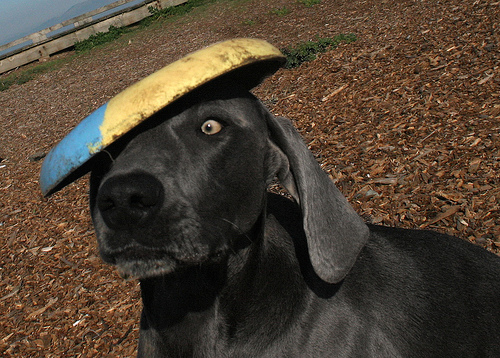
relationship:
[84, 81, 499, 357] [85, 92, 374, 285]
dog has head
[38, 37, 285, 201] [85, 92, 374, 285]
frisbee on top of head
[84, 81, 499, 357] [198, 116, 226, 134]
dog has eye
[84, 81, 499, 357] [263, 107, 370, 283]
dog has ear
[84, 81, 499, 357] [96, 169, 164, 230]
dog has nose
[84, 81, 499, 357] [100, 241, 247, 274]
dog has mouth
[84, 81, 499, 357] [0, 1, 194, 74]
dog in front of railing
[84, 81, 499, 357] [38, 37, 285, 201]
dog wearing frisbee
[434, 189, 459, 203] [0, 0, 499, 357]
wood chip on top of ground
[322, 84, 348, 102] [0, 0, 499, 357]
wood chip on top of ground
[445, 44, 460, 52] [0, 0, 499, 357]
wood chip on top of ground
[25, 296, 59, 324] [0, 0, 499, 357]
wood chip on top of ground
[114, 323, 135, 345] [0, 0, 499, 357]
wood chip on top of ground